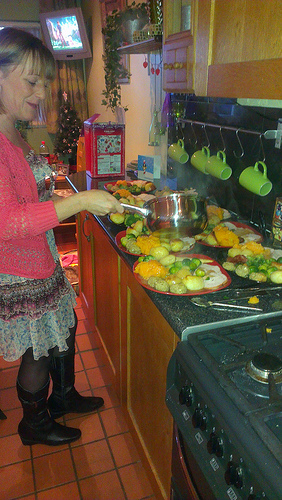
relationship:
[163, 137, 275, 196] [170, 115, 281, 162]
cups on hooks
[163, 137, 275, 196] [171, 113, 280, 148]
cups on hooks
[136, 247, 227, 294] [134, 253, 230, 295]
food on plate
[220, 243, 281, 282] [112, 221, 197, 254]
food on plate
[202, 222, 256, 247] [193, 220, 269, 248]
food on plate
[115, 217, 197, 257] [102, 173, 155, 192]
food on plate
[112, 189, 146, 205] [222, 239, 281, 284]
food on plate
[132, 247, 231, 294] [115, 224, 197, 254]
food on plate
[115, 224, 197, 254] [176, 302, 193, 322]
plate on counter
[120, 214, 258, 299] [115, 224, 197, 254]
food on plate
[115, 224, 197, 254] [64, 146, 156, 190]
plate on counter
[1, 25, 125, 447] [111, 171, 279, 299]
lady prepares meal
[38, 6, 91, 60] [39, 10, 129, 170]
monitor on wall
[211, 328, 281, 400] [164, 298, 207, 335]
range next to counter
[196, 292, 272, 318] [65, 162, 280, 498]
spoon on counter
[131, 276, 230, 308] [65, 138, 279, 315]
plate on counter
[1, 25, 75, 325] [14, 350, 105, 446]
lady wearing boots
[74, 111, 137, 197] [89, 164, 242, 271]
box on counter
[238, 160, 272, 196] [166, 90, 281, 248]
cup on wall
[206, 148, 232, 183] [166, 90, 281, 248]
cup on wall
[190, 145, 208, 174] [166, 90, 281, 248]
cup on wall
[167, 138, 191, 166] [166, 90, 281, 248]
cups on wall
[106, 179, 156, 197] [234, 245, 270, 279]
plate of food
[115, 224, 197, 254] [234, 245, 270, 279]
plate of food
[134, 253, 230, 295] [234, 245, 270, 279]
plate of food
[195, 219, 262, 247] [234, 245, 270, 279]
plate of food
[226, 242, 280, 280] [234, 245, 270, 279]
plate of food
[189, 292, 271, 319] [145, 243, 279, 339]
spoon rests on countertop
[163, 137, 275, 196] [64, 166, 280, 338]
cups hang above countertop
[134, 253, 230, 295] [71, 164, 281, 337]
plate on top of counter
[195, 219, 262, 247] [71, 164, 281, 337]
plate on top of counter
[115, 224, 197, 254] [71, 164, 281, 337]
plate on top of counter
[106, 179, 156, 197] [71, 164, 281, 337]
plate on top of counter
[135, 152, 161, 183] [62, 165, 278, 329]
card on top of counter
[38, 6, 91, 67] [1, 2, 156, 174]
monitor attached to wall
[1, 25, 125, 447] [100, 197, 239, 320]
lady serving meal